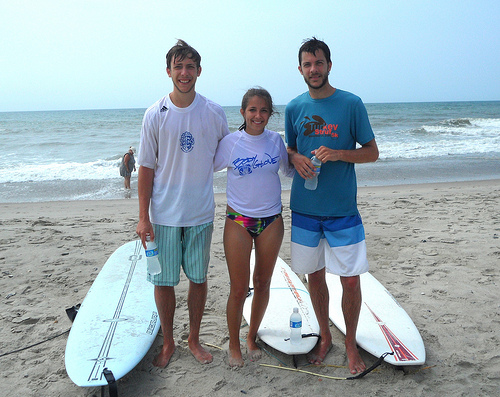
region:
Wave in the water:
[376, 114, 498, 159]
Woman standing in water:
[117, 144, 136, 189]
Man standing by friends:
[135, 38, 230, 369]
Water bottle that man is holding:
[142, 230, 162, 275]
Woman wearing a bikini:
[214, 86, 296, 368]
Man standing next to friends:
[282, 37, 379, 376]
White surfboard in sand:
[63, 235, 165, 395]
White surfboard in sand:
[237, 246, 320, 357]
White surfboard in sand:
[303, 256, 425, 366]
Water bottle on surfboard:
[289, 307, 302, 346]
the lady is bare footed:
[227, 336, 267, 370]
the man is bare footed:
[304, 325, 370, 374]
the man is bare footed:
[161, 337, 214, 379]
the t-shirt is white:
[141, 101, 223, 218]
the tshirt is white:
[218, 132, 280, 215]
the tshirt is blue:
[288, 92, 360, 212]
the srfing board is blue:
[68, 240, 145, 377]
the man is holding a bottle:
[136, 235, 163, 271]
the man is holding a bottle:
[306, 150, 328, 190]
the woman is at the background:
[117, 145, 134, 190]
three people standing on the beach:
[136, 38, 378, 374]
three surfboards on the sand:
[66, 234, 424, 382]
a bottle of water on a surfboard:
[289, 307, 303, 339]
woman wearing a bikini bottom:
[223, 212, 283, 236]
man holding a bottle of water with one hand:
[141, 232, 161, 273]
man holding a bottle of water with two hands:
[303, 150, 320, 189]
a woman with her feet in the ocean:
[119, 145, 137, 188]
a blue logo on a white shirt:
[178, 130, 195, 152]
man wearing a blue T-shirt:
[284, 89, 372, 214]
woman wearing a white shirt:
[215, 128, 292, 217]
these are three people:
[128, 134, 374, 224]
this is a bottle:
[254, 278, 331, 378]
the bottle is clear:
[257, 297, 331, 379]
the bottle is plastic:
[260, 310, 327, 360]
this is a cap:
[283, 285, 330, 326]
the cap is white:
[272, 295, 343, 353]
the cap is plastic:
[272, 300, 368, 365]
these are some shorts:
[302, 233, 359, 288]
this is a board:
[77, 325, 143, 389]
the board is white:
[83, 332, 108, 367]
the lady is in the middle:
[208, 80, 289, 314]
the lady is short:
[200, 86, 294, 268]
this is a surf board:
[85, 283, 147, 370]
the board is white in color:
[93, 275, 145, 350]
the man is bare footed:
[153, 282, 215, 369]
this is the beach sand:
[13, 212, 80, 263]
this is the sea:
[28, 109, 103, 161]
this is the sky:
[401, 4, 471, 85]